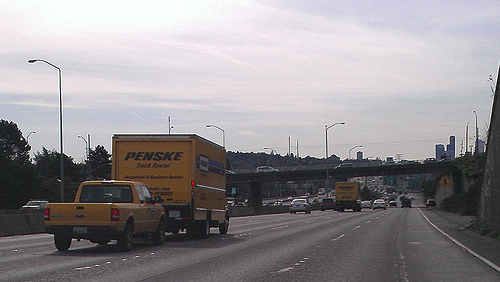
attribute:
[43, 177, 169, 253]
pickup truck — yellow, small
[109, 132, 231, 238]
truck — moving, yellow, bigger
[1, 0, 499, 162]
clouds — white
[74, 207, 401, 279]
lane stripes — white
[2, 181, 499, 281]
pavment — gray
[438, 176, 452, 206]
sign — yellow, on side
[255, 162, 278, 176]
car — white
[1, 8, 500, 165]
sky — blue, cloudy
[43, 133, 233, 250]
two trucks — moving, driving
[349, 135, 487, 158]
buildings — tall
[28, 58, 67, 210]
street light — metal, tall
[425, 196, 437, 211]
car — pulled over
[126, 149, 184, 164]
letters — black